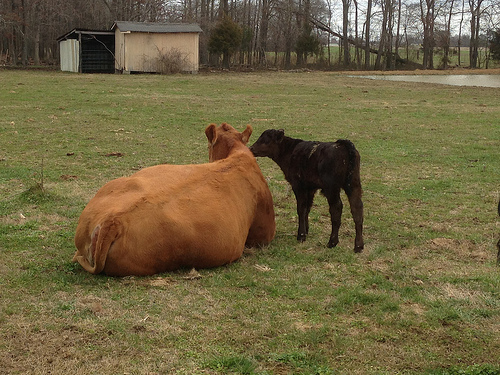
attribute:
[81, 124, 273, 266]
cow — peaceful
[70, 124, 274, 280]
cow — brown, big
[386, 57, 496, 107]
pond — small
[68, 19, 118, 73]
shed — metal, small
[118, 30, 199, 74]
building — small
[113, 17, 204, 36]
roof — grey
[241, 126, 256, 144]
cow ear — brown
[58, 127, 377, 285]
cows — waiting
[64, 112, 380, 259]
cow — large, brown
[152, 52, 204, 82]
bush — bare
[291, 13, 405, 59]
tree — fallen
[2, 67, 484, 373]
grass — brown, green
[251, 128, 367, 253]
calf — black, baby, small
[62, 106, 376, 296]
cows — out